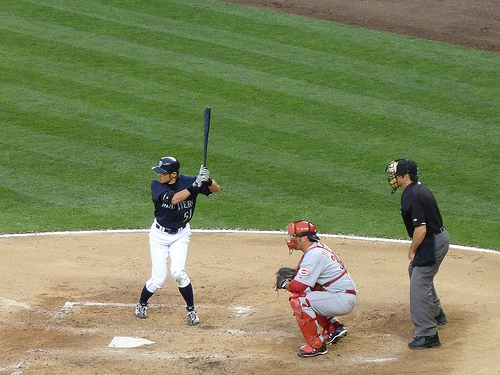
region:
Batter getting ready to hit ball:
[132, 148, 222, 324]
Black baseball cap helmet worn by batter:
[146, 151, 182, 176]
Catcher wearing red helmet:
[281, 215, 317, 235]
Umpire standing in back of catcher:
[382, 155, 453, 351]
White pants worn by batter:
[142, 216, 195, 291]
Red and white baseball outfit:
[286, 240, 356, 355]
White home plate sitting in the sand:
[105, 331, 160, 357]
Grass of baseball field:
[5, 0, 495, 251]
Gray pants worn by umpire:
[407, 226, 448, 334]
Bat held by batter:
[197, 102, 215, 168]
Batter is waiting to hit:
[134, 108, 216, 327]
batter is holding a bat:
[127, 107, 220, 324]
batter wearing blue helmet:
[130, 111, 218, 327]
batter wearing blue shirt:
[135, 156, 223, 328]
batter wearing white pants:
[137, 153, 219, 326]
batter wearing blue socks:
[134, 155, 219, 326]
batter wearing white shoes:
[133, 153, 218, 328]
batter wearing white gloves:
[135, 155, 214, 325]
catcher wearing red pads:
[276, 221, 356, 358]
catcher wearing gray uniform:
[267, 218, 359, 362]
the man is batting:
[116, 51, 230, 331]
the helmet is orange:
[278, 217, 319, 237]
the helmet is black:
[142, 134, 187, 180]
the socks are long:
[135, 282, 201, 311]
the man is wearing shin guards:
[284, 291, 324, 353]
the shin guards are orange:
[285, 295, 329, 358]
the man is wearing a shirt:
[392, 188, 449, 233]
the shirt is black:
[395, 190, 442, 235]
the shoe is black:
[397, 330, 444, 353]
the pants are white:
[147, 220, 194, 292]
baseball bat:
[203, 106, 209, 166]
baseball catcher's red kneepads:
[286, 296, 319, 345]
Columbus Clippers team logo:
[300, 267, 309, 276]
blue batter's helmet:
[150, 156, 180, 174]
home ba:
[109, 337, 156, 349]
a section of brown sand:
[34, 252, 84, 288]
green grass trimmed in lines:
[285, 67, 383, 173]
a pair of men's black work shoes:
[406, 331, 440, 348]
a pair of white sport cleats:
[130, 303, 199, 323]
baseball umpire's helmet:
[386, 159, 416, 194]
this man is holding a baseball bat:
[133, 104, 219, 327]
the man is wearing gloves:
[192, 159, 214, 191]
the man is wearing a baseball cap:
[149, 154, 183, 173]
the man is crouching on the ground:
[274, 217, 361, 359]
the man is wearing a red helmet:
[278, 216, 316, 251]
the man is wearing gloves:
[271, 266, 301, 289]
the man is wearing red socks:
[287, 299, 344, 359]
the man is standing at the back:
[385, 159, 448, 353]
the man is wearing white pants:
[140, 212, 192, 292]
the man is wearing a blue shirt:
[142, 173, 212, 230]